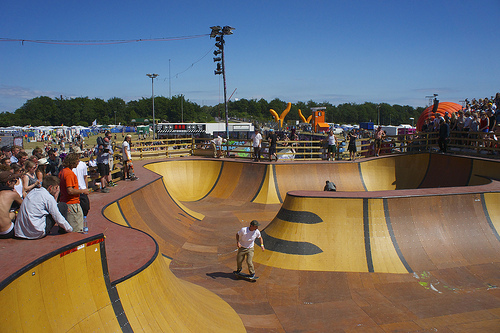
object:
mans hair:
[41, 175, 61, 186]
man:
[13, 175, 74, 241]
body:
[233, 220, 266, 276]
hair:
[63, 151, 81, 168]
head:
[250, 220, 262, 231]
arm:
[236, 227, 245, 248]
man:
[56, 153, 91, 233]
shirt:
[56, 167, 78, 204]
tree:
[383, 104, 396, 126]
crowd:
[309, 125, 372, 162]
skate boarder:
[227, 217, 265, 282]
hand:
[261, 246, 266, 252]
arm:
[256, 232, 265, 252]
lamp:
[208, 22, 236, 141]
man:
[78, 150, 93, 227]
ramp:
[4, 152, 499, 332]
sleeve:
[234, 227, 246, 236]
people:
[99, 135, 115, 194]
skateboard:
[232, 270, 260, 282]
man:
[233, 219, 267, 278]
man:
[0, 168, 24, 238]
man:
[121, 132, 133, 181]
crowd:
[398, 93, 498, 148]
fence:
[118, 130, 498, 161]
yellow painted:
[323, 203, 386, 262]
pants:
[235, 245, 255, 275]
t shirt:
[237, 226, 260, 250]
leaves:
[113, 104, 136, 114]